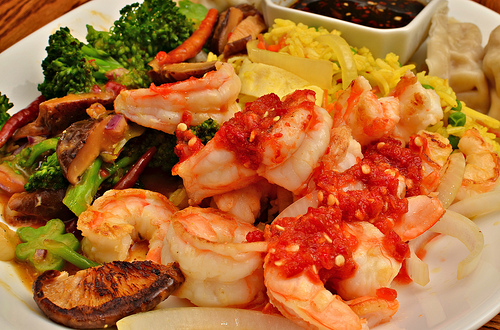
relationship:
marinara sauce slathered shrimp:
[215, 89, 320, 169] [74, 184, 265, 310]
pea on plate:
[441, 105, 470, 147] [0, 1, 498, 327]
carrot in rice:
[256, 33, 290, 50] [205, 17, 497, 147]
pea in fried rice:
[441, 105, 470, 147] [250, 15, 475, 201]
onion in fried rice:
[319, 31, 359, 89] [242, 10, 485, 138]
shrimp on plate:
[183, 93, 426, 330] [1, 208, 498, 328]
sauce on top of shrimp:
[264, 205, 358, 282] [183, 93, 426, 330]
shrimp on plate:
[254, 99, 332, 194] [0, 1, 498, 327]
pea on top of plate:
[448, 108, 466, 127] [0, 1, 498, 327]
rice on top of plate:
[257, 19, 404, 90] [400, 273, 496, 328]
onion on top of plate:
[319, 31, 359, 89] [0, 1, 498, 327]